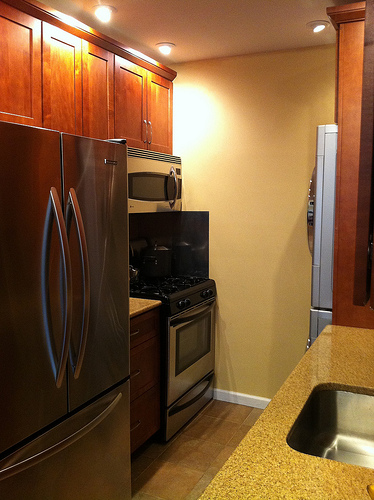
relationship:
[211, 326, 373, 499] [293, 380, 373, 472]
counter of sink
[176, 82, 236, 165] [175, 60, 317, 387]
light shining on wall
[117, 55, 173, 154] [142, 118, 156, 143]
cupboard has handles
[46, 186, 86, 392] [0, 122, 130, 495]
handles on front of refrigerator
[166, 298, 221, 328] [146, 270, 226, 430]
handle of oven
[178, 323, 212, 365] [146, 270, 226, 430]
window on door of oven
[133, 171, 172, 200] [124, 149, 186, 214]
window on front of microwave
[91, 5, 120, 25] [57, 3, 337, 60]
light on top of ceiling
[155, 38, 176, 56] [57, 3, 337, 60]
light on top of ceiling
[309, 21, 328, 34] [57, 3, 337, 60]
light on top of ceiling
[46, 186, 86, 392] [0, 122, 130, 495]
handles for refrigerator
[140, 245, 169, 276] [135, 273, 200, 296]
pot atop stove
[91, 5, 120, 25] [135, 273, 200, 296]
light over stove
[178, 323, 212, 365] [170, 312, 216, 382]
window on front of door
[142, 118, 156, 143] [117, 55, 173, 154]
handles on front of cupboard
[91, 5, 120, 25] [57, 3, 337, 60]
light hanging from ceiling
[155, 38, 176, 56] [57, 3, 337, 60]
light hanging from ceiling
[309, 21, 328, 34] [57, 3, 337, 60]
light hanging from ceiling